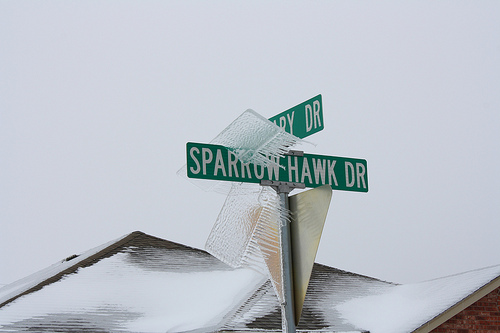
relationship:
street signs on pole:
[137, 108, 379, 241] [278, 279, 307, 305]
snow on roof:
[162, 282, 211, 302] [124, 231, 168, 248]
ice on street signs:
[227, 111, 301, 156] [137, 108, 379, 241]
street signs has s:
[137, 108, 379, 241] [182, 137, 197, 178]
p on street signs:
[201, 143, 211, 178] [137, 108, 379, 241]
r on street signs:
[231, 147, 238, 182] [137, 108, 379, 241]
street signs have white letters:
[137, 108, 379, 241] [307, 109, 324, 127]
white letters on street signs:
[307, 109, 324, 127] [137, 108, 379, 241]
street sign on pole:
[174, 132, 380, 203] [278, 279, 307, 305]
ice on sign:
[227, 111, 301, 156] [223, 200, 320, 302]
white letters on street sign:
[307, 109, 324, 127] [174, 132, 380, 203]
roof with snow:
[124, 231, 168, 248] [162, 282, 211, 302]